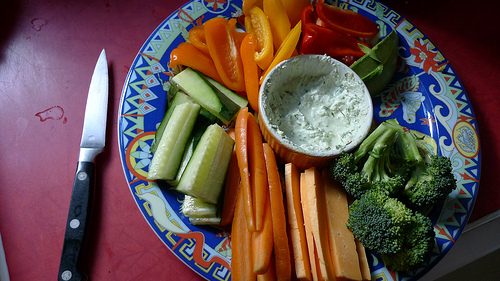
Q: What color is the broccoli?
A: Green.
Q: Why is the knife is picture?
A: To cut vegetables.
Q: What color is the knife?
A: Black.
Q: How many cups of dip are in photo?
A: One.